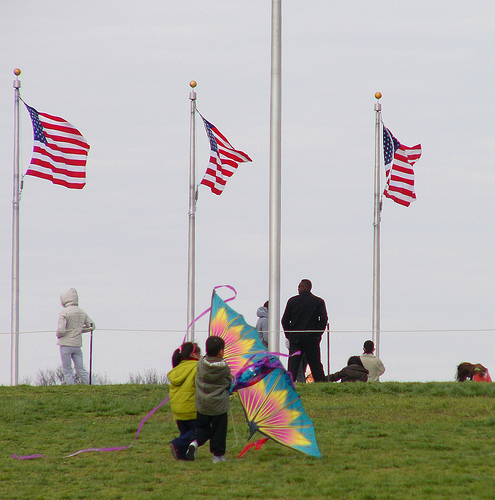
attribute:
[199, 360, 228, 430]
jacket — yellow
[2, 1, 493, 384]
sky — grey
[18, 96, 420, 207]
flags — american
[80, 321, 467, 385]
fence — metal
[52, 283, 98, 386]
person — hooded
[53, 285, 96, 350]
jacket — white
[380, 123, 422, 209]
flag — United States of America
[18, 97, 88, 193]
flag — United States of America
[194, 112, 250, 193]
flag — United States of America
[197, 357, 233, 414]
jacket — winter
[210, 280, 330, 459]
kite — big, colorful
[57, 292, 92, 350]
coat — white, hooded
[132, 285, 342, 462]
children — small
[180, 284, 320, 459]
kite — multicolored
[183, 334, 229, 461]
boy — little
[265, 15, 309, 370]
flagpole — tall, metal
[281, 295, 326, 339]
jacket — black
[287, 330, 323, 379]
pants — black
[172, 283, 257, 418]
jacket — gray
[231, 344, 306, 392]
ribbons — purple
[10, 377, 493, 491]
grassy — green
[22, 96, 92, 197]
flag — American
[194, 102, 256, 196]
flag — American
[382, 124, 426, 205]
flag — American